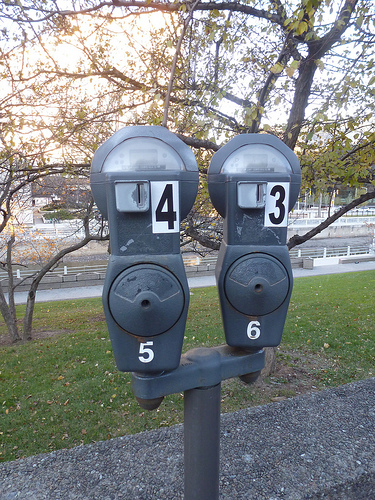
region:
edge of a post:
[140, 118, 179, 146]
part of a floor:
[279, 424, 317, 468]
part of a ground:
[45, 393, 95, 446]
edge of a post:
[177, 443, 193, 485]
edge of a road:
[320, 477, 345, 495]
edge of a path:
[265, 380, 300, 404]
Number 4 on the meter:
[140, 173, 188, 240]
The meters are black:
[68, 131, 308, 490]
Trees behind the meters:
[0, 6, 341, 287]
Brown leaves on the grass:
[17, 261, 366, 473]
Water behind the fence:
[5, 211, 315, 295]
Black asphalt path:
[40, 381, 364, 497]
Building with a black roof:
[14, 165, 115, 219]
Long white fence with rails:
[7, 240, 367, 291]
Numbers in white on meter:
[102, 303, 286, 389]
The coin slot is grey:
[103, 174, 170, 222]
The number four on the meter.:
[141, 167, 187, 244]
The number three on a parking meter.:
[256, 176, 302, 240]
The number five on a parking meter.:
[122, 322, 167, 384]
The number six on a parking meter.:
[223, 301, 280, 387]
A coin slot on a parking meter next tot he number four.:
[115, 170, 163, 230]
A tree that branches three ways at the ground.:
[0, 155, 86, 355]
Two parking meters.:
[81, 115, 307, 410]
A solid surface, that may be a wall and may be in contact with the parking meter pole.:
[8, 378, 370, 491]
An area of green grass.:
[310, 279, 370, 341]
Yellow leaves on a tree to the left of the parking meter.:
[4, 213, 67, 286]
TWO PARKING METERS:
[70, 117, 305, 430]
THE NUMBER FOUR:
[146, 177, 196, 240]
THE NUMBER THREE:
[261, 176, 295, 233]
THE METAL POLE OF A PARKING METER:
[175, 374, 229, 498]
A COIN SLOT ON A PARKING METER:
[113, 176, 156, 217]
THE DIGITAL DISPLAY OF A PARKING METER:
[218, 137, 295, 179]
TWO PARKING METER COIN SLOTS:
[109, 173, 272, 215]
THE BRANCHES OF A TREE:
[207, 5, 350, 128]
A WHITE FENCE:
[10, 259, 107, 282]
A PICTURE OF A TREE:
[0, 100, 98, 343]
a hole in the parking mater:
[135, 295, 150, 313]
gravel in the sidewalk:
[267, 411, 342, 494]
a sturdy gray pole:
[187, 395, 217, 495]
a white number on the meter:
[137, 336, 162, 369]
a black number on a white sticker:
[154, 184, 185, 234]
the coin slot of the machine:
[126, 183, 150, 204]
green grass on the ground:
[321, 278, 360, 328]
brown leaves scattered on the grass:
[19, 378, 119, 428]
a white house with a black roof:
[33, 189, 57, 207]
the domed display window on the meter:
[113, 137, 183, 175]